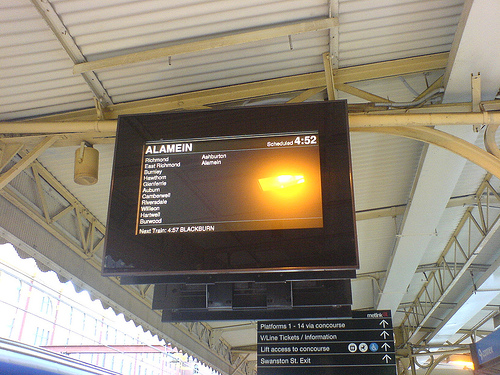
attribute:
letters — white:
[258, 321, 347, 329]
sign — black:
[153, 280, 353, 324]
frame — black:
[117, 101, 347, 145]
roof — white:
[0, 2, 485, 326]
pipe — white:
[370, 84, 442, 108]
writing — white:
[140, 156, 186, 225]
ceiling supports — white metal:
[397, 200, 484, 337]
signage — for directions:
[254, 306, 400, 373]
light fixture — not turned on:
[72, 138, 100, 186]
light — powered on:
[443, 352, 476, 369]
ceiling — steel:
[4, 11, 447, 100]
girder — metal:
[41, 338, 168, 358]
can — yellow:
[70, 138, 100, 188]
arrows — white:
[375, 313, 393, 363]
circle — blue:
[368, 340, 380, 354]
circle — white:
[355, 338, 371, 354]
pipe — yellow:
[4, 118, 118, 138]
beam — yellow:
[135, 56, 444, 105]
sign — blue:
[464, 325, 498, 372]